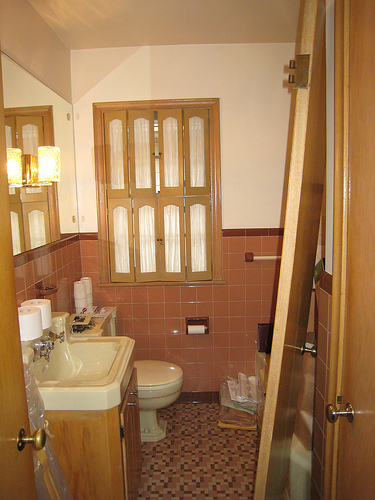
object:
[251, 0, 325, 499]
door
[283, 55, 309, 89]
hinges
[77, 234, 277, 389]
bathroom wall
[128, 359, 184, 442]
commode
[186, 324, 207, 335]
holder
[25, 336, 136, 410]
sink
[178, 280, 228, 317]
tiles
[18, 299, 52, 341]
rolls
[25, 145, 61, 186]
light mounted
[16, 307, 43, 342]
toilet roll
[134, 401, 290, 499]
floor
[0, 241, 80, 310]
wall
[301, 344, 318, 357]
knob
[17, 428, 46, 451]
door knob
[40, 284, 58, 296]
soap dish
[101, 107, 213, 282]
paneled shutters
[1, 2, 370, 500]
bathroom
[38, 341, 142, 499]
cabinet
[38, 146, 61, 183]
light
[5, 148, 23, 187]
light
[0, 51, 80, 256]
mirror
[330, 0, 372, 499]
door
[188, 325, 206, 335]
toilet paper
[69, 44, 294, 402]
wall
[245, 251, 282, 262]
rod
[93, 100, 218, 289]
window frame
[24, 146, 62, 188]
fixture